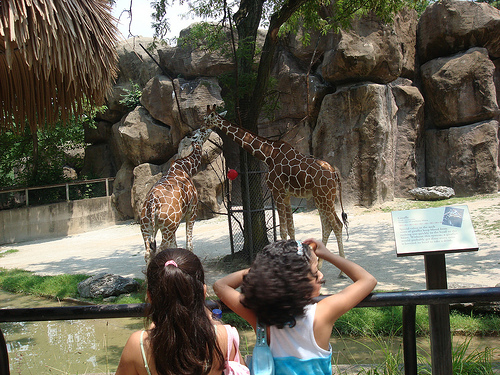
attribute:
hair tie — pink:
[161, 260, 182, 268]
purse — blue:
[249, 321, 275, 375]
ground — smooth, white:
[1, 186, 500, 334]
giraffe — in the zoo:
[204, 105, 350, 279]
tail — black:
[334, 172, 352, 237]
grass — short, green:
[380, 198, 475, 210]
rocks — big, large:
[102, 0, 498, 221]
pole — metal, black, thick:
[239, 139, 257, 266]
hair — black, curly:
[239, 240, 313, 326]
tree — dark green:
[216, 0, 431, 262]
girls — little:
[112, 239, 378, 374]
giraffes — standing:
[140, 102, 354, 281]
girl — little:
[210, 237, 372, 375]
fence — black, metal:
[1, 284, 500, 375]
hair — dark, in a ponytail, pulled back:
[144, 247, 228, 374]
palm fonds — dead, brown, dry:
[1, 1, 120, 127]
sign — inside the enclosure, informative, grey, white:
[390, 204, 480, 255]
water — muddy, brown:
[1, 290, 499, 374]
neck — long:
[220, 121, 272, 162]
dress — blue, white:
[261, 302, 333, 374]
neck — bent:
[171, 148, 206, 174]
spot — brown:
[227, 124, 239, 135]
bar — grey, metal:
[246, 164, 267, 176]